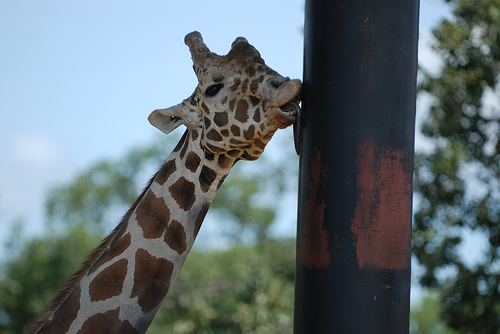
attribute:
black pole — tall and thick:
[291, 0, 423, 333]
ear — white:
[117, 84, 202, 140]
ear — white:
[136, 99, 195, 137]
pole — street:
[261, 18, 473, 321]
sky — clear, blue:
[3, 4, 498, 281]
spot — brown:
[128, 246, 173, 314]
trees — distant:
[5, 125, 290, 332]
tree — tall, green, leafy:
[419, 5, 498, 332]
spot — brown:
[153, 206, 185, 266]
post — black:
[294, 0, 414, 331]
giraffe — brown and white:
[95, 32, 306, 265]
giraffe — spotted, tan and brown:
[22, 25, 302, 330]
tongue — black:
[291, 100, 304, 155]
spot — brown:
[138, 190, 169, 245]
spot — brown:
[150, 155, 177, 184]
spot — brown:
[87, 255, 130, 301]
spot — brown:
[181, 148, 203, 173]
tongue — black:
[283, 99, 305, 156]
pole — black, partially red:
[294, 3, 419, 330]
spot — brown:
[89, 259, 126, 300]